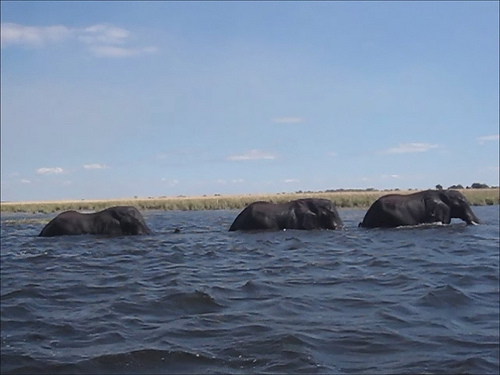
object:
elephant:
[358, 190, 477, 228]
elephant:
[227, 198, 342, 232]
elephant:
[40, 206, 180, 236]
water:
[0, 203, 498, 371]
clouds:
[0, 17, 158, 57]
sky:
[0, 0, 499, 205]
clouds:
[17, 161, 63, 187]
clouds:
[227, 152, 272, 159]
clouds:
[269, 116, 301, 121]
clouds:
[375, 143, 436, 153]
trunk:
[463, 209, 479, 225]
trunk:
[143, 225, 152, 235]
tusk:
[471, 221, 477, 225]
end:
[173, 228, 179, 233]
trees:
[471, 183, 489, 189]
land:
[1, 188, 498, 213]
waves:
[19, 350, 239, 375]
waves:
[157, 290, 222, 307]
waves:
[412, 284, 473, 301]